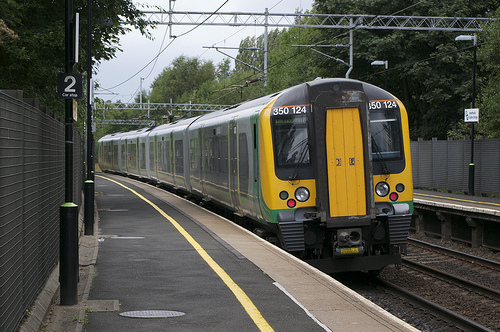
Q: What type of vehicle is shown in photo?
A: Train.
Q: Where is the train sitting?
A: On tracks.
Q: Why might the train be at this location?
A: To pick up passengers.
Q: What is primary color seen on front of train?
A: Yellow.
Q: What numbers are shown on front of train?
A: 350 124.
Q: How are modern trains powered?
A: By engines.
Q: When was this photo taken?
A: Daytime.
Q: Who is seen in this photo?
A: Noone.